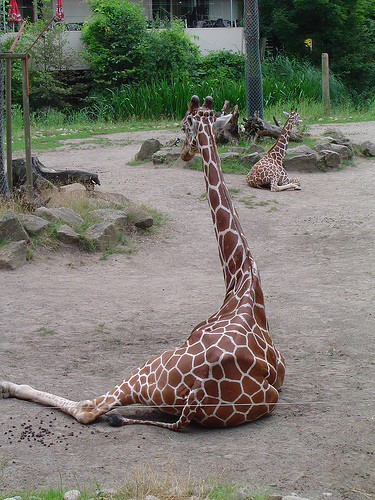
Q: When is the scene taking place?
A: Daytime.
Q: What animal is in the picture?
A: Giraffe.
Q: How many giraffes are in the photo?
A: Two.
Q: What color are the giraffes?
A: Brown and white.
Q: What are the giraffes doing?
A: Lying down.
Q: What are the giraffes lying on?
A: Dirt.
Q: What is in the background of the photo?
A: Foliage and trees.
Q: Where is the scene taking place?
A: In a game preserve.